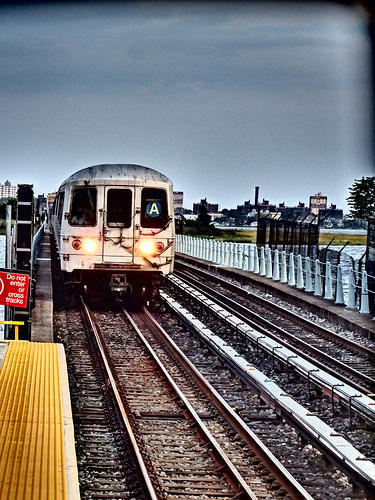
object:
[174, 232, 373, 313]
fence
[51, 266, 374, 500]
train tracks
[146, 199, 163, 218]
blue sign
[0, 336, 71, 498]
grate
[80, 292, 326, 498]
tracks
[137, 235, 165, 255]
light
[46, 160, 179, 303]
train